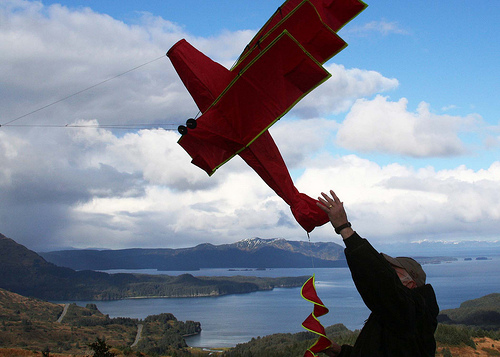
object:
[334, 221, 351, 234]
bracelet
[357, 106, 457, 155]
cloud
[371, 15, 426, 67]
sky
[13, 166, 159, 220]
clouds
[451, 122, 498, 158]
cloud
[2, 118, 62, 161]
cloud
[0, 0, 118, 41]
cloud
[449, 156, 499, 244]
cloud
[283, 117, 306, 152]
clouds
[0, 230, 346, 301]
mountains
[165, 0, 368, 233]
airplane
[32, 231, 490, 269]
land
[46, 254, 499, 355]
water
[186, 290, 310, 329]
lake water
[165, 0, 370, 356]
kite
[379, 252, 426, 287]
baseball cap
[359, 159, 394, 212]
clouds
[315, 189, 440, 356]
man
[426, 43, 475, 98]
sky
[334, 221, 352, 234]
watch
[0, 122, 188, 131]
string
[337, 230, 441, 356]
jacket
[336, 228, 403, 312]
arm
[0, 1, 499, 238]
distance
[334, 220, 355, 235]
wrist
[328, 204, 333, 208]
ring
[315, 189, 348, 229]
hand